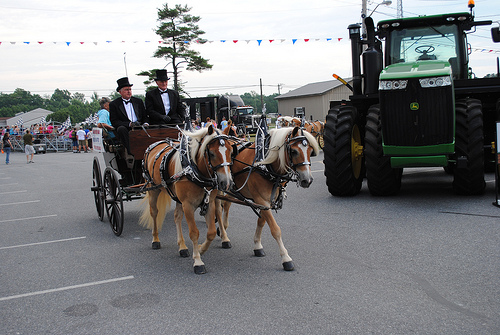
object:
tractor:
[324, 0, 500, 198]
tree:
[136, 2, 217, 97]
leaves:
[153, 0, 183, 18]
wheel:
[90, 156, 106, 222]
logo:
[409, 102, 420, 111]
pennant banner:
[0, 37, 499, 54]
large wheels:
[102, 165, 123, 237]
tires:
[322, 105, 366, 197]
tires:
[452, 121, 486, 219]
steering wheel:
[415, 45, 436, 54]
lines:
[0, 273, 138, 302]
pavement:
[0, 150, 499, 333]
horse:
[216, 126, 318, 271]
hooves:
[193, 264, 208, 274]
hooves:
[281, 260, 294, 270]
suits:
[145, 87, 189, 124]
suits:
[109, 95, 150, 128]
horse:
[138, 121, 236, 275]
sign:
[91, 127, 106, 153]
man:
[97, 97, 121, 145]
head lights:
[418, 76, 451, 88]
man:
[147, 69, 185, 126]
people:
[22, 129, 36, 164]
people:
[2, 132, 13, 165]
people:
[13, 125, 20, 141]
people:
[39, 123, 44, 138]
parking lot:
[2, 111, 499, 335]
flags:
[256, 40, 262, 46]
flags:
[487, 49, 493, 53]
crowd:
[11, 117, 97, 165]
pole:
[259, 78, 264, 113]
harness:
[139, 137, 189, 205]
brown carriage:
[90, 122, 202, 236]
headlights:
[378, 79, 408, 90]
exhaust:
[364, 16, 376, 49]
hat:
[154, 69, 170, 81]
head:
[119, 84, 133, 98]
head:
[156, 77, 169, 88]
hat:
[116, 77, 133, 92]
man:
[109, 77, 150, 177]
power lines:
[7, 82, 295, 92]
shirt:
[97, 109, 116, 139]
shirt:
[3, 135, 11, 147]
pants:
[3, 146, 11, 163]